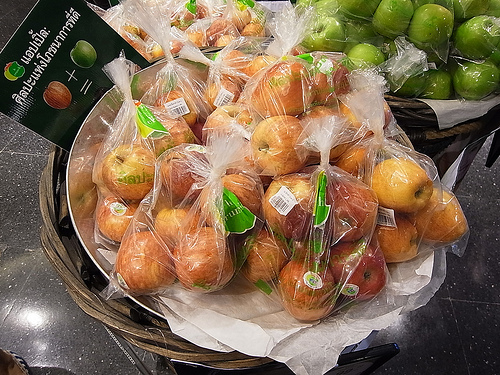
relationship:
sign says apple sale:
[0, 2, 185, 136] [66, 32, 486, 326]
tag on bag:
[269, 191, 300, 216] [239, 99, 382, 324]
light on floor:
[9, 297, 51, 340] [2, 108, 496, 371]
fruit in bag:
[121, 232, 171, 292] [128, 122, 278, 294]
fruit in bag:
[175, 224, 227, 295] [128, 122, 278, 294]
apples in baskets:
[314, 0, 454, 67] [378, 70, 498, 204]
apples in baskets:
[451, 12, 498, 101] [378, 70, 498, 204]